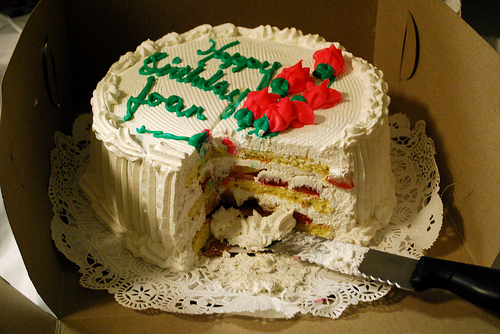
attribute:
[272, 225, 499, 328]
knife — black, metal, blade, serrated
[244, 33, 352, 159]
roses — red, pink, frosting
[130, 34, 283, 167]
words — green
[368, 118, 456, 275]
dolly — cake covered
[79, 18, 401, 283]
cake — white, orange, layers, birthday, layered, joan, missing slice, strawberry, ridged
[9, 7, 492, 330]
cardboard — box, brown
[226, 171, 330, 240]
filing — red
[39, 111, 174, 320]
paper — white